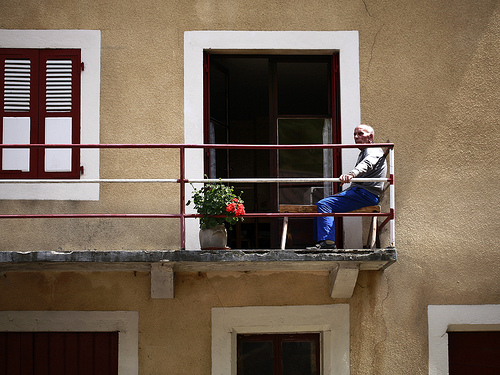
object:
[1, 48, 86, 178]
blinds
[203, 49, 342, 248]
door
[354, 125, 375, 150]
head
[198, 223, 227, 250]
pot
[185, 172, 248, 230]
plant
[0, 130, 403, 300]
patio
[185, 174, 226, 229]
green leaves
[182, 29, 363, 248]
doorway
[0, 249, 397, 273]
floor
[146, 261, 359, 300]
supports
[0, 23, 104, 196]
window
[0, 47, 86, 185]
table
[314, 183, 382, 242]
blue jeans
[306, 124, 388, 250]
man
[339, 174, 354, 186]
hand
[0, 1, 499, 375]
wall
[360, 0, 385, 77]
crack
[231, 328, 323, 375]
window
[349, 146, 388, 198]
jacket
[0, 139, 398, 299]
balcony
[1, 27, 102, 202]
frame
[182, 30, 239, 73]
corner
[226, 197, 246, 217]
flower